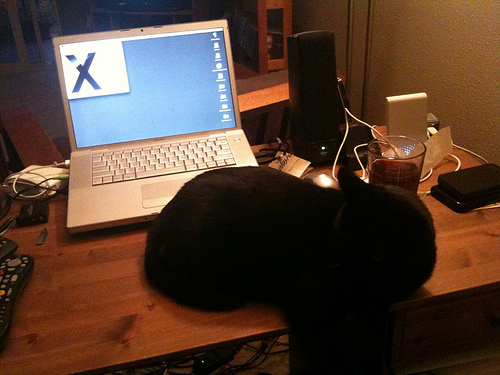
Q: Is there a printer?
A: No, there are no printers.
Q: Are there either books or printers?
A: No, there are no printers or books.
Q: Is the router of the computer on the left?
A: Yes, the router is on the left of the image.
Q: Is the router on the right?
A: No, the router is on the left of the image.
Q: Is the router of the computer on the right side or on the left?
A: The router is on the left of the image.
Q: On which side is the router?
A: The router is on the left of the image.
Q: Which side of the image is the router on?
A: The router is on the left of the image.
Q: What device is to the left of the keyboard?
A: The device is a router.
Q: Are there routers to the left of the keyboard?
A: Yes, there is a router to the left of the keyboard.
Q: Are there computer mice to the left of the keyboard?
A: No, there is a router to the left of the keyboard.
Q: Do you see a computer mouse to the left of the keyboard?
A: No, there is a router to the left of the keyboard.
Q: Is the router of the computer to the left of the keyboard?
A: Yes, the router is to the left of the keyboard.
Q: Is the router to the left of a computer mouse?
A: No, the router is to the left of the keyboard.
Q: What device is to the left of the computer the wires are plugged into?
A: The device is a router.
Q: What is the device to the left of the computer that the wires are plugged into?
A: The device is a router.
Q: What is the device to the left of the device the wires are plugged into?
A: The device is a router.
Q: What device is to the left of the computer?
A: The device is a router.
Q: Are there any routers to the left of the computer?
A: Yes, there is a router to the left of the computer.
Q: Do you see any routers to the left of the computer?
A: Yes, there is a router to the left of the computer.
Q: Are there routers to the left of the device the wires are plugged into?
A: Yes, there is a router to the left of the computer.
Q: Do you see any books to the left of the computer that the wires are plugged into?
A: No, there is a router to the left of the computer.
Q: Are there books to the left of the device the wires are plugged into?
A: No, there is a router to the left of the computer.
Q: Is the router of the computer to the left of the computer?
A: Yes, the router is to the left of the computer.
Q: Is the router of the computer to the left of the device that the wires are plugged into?
A: Yes, the router is to the left of the computer.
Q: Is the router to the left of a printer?
A: No, the router is to the left of the computer.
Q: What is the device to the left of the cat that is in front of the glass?
A: The device is a router.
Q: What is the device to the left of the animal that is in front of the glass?
A: The device is a router.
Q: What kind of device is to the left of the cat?
A: The device is a router.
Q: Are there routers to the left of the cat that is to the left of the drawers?
A: Yes, there is a router to the left of the cat.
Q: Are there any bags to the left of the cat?
A: No, there is a router to the left of the cat.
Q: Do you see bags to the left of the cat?
A: No, there is a router to the left of the cat.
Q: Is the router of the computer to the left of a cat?
A: Yes, the router is to the left of a cat.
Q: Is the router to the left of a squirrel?
A: No, the router is to the left of a cat.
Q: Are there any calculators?
A: No, there are no calculators.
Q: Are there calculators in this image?
A: No, there are no calculators.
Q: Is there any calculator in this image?
A: No, there are no calculators.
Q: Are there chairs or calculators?
A: No, there are no calculators or chairs.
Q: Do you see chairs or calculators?
A: No, there are no calculators or chairs.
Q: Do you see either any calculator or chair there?
A: No, there are no calculators or chairs.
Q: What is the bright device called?
A: The device is a screen.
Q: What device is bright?
A: The device is a screen.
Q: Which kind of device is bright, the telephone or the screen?
A: The screen is bright.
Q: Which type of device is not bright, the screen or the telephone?
A: The telephone is not bright.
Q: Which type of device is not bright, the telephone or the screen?
A: The telephone is not bright.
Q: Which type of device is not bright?
A: The device is a phone.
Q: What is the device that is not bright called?
A: The device is a phone.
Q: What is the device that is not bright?
A: The device is a phone.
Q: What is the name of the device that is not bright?
A: The device is a phone.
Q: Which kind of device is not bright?
A: The device is a phone.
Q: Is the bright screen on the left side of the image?
A: Yes, the screen is on the left of the image.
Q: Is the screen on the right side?
A: No, the screen is on the left of the image.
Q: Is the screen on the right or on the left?
A: The screen is on the left of the image.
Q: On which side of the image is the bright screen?
A: The screen is on the left of the image.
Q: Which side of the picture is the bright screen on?
A: The screen is on the left of the image.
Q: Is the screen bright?
A: Yes, the screen is bright.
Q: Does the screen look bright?
A: Yes, the screen is bright.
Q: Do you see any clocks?
A: No, there are no clocks.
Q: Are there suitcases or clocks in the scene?
A: No, there are no clocks or suitcases.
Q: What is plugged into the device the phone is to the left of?
A: The wires are plugged into the computer.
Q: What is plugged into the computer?
A: The wires are plugged into the computer.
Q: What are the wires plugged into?
A: The wires are plugged into the computer.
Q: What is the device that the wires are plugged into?
A: The device is a computer.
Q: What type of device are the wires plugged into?
A: The wires are plugged into the computer.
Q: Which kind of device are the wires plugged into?
A: The wires are plugged into the computer.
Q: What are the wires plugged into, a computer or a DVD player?
A: The wires are plugged into a computer.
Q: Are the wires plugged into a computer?
A: Yes, the wires are plugged into a computer.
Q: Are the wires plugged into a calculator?
A: No, the wires are plugged into a computer.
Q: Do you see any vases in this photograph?
A: No, there are no vases.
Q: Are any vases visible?
A: No, there are no vases.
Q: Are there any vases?
A: No, there are no vases.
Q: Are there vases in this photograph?
A: No, there are no vases.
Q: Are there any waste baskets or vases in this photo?
A: No, there are no vases or waste baskets.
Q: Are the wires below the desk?
A: Yes, the wires are below the desk.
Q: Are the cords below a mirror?
A: No, the cords are below the desk.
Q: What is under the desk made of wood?
A: The wires are under the desk.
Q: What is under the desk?
A: The wires are under the desk.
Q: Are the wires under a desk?
A: Yes, the wires are under a desk.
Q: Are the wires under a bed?
A: No, the wires are under a desk.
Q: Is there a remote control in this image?
A: Yes, there is a remote control.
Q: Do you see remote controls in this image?
A: Yes, there is a remote control.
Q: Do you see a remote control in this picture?
A: Yes, there is a remote control.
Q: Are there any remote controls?
A: Yes, there is a remote control.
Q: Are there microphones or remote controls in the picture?
A: Yes, there is a remote control.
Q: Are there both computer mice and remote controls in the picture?
A: No, there is a remote control but no computer mice.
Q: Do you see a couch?
A: No, there are no couches.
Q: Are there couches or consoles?
A: No, there are no couches or consoles.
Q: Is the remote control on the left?
A: Yes, the remote control is on the left of the image.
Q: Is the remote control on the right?
A: No, the remote control is on the left of the image.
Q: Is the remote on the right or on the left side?
A: The remote is on the left of the image.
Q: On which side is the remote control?
A: The remote control is on the left of the image.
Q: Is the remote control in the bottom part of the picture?
A: Yes, the remote control is in the bottom of the image.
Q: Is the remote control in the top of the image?
A: No, the remote control is in the bottom of the image.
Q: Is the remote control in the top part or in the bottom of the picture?
A: The remote control is in the bottom of the image.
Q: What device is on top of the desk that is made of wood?
A: The device is a remote control.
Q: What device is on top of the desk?
A: The device is a remote control.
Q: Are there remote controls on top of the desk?
A: Yes, there is a remote control on top of the desk.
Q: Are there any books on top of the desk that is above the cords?
A: No, there is a remote control on top of the desk.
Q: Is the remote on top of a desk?
A: Yes, the remote is on top of a desk.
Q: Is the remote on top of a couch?
A: No, the remote is on top of a desk.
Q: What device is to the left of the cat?
A: The device is a remote control.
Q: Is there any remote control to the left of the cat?
A: Yes, there is a remote control to the left of the cat.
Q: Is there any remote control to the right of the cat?
A: No, the remote control is to the left of the cat.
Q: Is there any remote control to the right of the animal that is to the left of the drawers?
A: No, the remote control is to the left of the cat.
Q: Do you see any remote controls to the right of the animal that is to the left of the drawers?
A: No, the remote control is to the left of the cat.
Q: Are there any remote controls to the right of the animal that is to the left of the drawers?
A: No, the remote control is to the left of the cat.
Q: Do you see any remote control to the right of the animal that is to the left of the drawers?
A: No, the remote control is to the left of the cat.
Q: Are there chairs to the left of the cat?
A: No, there is a remote control to the left of the cat.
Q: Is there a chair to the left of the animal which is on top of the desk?
A: No, there is a remote control to the left of the cat.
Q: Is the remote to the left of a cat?
A: Yes, the remote is to the left of a cat.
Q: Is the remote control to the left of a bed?
A: No, the remote control is to the left of a cat.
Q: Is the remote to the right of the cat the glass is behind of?
A: No, the remote is to the left of the cat.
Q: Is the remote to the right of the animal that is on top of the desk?
A: No, the remote is to the left of the cat.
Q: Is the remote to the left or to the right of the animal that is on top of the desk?
A: The remote is to the left of the cat.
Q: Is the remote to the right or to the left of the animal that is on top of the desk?
A: The remote is to the left of the cat.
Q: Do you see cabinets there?
A: No, there are no cabinets.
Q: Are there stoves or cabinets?
A: No, there are no cabinets or stoves.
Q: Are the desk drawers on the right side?
A: Yes, the drawers are on the right of the image.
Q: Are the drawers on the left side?
A: No, the drawers are on the right of the image.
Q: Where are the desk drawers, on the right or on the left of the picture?
A: The drawers are on the right of the image.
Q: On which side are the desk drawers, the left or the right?
A: The drawers are on the right of the image.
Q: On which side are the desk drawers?
A: The drawers are on the right of the image.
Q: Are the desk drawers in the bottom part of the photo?
A: Yes, the drawers are in the bottom of the image.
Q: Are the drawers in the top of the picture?
A: No, the drawers are in the bottom of the image.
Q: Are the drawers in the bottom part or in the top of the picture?
A: The drawers are in the bottom of the image.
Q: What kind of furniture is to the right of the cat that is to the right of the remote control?
A: The pieces of furniture are drawers.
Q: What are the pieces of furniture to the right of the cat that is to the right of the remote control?
A: The pieces of furniture are drawers.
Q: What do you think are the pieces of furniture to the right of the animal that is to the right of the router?
A: The pieces of furniture are drawers.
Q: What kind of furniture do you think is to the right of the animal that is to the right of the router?
A: The pieces of furniture are drawers.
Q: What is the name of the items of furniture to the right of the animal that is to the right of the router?
A: The pieces of furniture are drawers.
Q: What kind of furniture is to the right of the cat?
A: The pieces of furniture are drawers.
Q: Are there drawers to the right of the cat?
A: Yes, there are drawers to the right of the cat.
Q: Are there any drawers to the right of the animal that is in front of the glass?
A: Yes, there are drawers to the right of the cat.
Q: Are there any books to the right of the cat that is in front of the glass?
A: No, there are drawers to the right of the cat.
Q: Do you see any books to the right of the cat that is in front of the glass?
A: No, there are drawers to the right of the cat.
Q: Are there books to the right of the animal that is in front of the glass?
A: No, there are drawers to the right of the cat.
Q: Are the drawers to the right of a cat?
A: Yes, the drawers are to the right of a cat.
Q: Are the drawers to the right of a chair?
A: No, the drawers are to the right of a cat.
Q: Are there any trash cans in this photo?
A: No, there are no trash cans.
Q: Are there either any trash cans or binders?
A: No, there are no trash cans or binders.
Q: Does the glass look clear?
A: Yes, the glass is clear.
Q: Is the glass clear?
A: Yes, the glass is clear.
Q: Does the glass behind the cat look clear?
A: Yes, the glass is clear.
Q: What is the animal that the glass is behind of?
A: The animal is a cat.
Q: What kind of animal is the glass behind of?
A: The glass is behind the cat.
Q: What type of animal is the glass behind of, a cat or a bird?
A: The glass is behind a cat.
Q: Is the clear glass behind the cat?
A: Yes, the glass is behind the cat.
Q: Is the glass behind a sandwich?
A: No, the glass is behind the cat.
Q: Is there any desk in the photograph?
A: Yes, there is a desk.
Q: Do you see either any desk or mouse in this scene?
A: Yes, there is a desk.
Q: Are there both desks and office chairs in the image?
A: No, there is a desk but no office chairs.